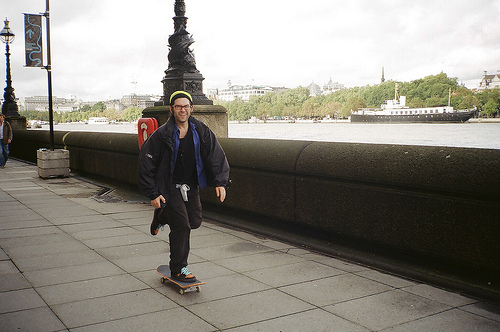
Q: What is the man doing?
A: Skateboarding.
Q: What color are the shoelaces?
A: Aqua.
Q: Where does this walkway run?
A: Near a river.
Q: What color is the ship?
A: Black and white.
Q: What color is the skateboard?
A: Black and orange.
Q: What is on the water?
A: Boat.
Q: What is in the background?
A: Buildings.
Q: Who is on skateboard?
A: Young man.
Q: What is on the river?
A: A boat.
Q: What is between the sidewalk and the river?
A: A wall.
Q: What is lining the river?
A: Trees.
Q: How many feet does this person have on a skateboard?
A: One.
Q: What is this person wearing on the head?
A: A stocking cap.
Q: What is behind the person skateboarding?
A: A light pole where the lamp isn't visible.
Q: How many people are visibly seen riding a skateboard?
A: One.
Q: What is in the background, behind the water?
A: Trees.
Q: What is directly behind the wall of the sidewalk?
A: A body of water.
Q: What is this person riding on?
A: A skateboard.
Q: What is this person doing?
A: Skateboarding.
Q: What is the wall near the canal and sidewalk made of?
A: Concrete.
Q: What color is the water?
A: Blue.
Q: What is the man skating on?
A: A bridge.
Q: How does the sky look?
A: White.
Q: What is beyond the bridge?
A: Water.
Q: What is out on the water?
A: A boat.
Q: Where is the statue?
A: The water.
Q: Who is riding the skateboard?
A: A man.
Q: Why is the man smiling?
A: He's happy.